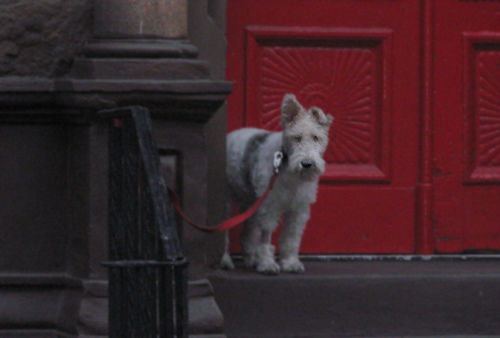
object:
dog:
[220, 94, 334, 275]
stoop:
[204, 256, 499, 337]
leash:
[166, 140, 289, 233]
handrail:
[96, 106, 188, 338]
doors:
[227, 1, 499, 256]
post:
[54, 1, 233, 338]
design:
[263, 46, 373, 165]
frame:
[242, 25, 394, 183]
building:
[101, 0, 497, 338]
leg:
[256, 206, 282, 261]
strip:
[241, 132, 277, 201]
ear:
[309, 107, 334, 127]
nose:
[300, 161, 313, 169]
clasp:
[274, 151, 283, 174]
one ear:
[282, 92, 303, 122]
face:
[283, 113, 329, 175]